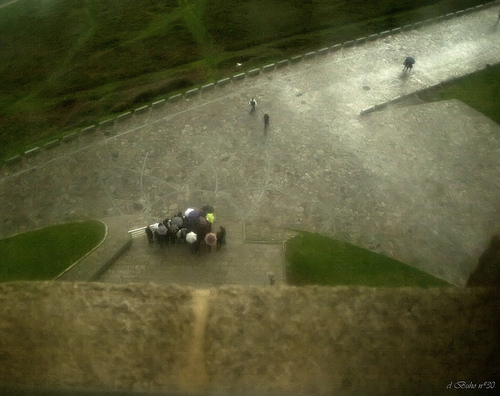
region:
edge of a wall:
[238, 258, 279, 295]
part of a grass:
[301, 238, 343, 293]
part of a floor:
[342, 192, 371, 242]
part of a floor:
[231, 252, 250, 282]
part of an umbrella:
[199, 224, 216, 271]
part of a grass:
[306, 235, 333, 278]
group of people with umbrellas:
[136, 193, 243, 248]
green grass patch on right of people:
[260, 202, 444, 302]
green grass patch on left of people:
[9, 205, 140, 283]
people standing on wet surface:
[139, 191, 231, 247]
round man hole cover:
[354, 80, 377, 94]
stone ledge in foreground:
[34, 263, 492, 370]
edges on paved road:
[52, 67, 246, 139]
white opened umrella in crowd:
[183, 225, 199, 247]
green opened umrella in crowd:
[209, 215, 219, 230]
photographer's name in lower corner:
[427, 370, 499, 392]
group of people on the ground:
[111, 187, 253, 262]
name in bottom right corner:
[436, 378, 498, 394]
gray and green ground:
[293, 204, 365, 269]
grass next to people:
[28, 228, 73, 265]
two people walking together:
[223, 84, 299, 146]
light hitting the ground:
[327, 73, 382, 103]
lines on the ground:
[123, 146, 193, 192]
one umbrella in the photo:
[202, 229, 217, 254]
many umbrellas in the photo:
[162, 204, 227, 254]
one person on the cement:
[254, 110, 281, 139]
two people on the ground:
[217, 95, 309, 137]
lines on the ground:
[148, 142, 263, 189]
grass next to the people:
[308, 245, 346, 272]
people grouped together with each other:
[154, 190, 236, 250]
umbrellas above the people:
[158, 200, 224, 247]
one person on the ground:
[246, 111, 282, 133]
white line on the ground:
[186, 88, 228, 121]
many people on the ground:
[3, 36, 464, 331]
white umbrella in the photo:
[183, 228, 197, 249]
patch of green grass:
[151, 39, 158, 56]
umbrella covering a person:
[204, 232, 217, 249]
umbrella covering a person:
[183, 232, 201, 246]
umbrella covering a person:
[158, 227, 171, 243]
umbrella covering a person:
[206, 211, 218, 221]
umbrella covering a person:
[173, 217, 180, 225]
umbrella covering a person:
[201, 202, 214, 209]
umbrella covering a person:
[190, 205, 196, 219]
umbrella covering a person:
[168, 215, 179, 225]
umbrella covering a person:
[157, 226, 166, 235]